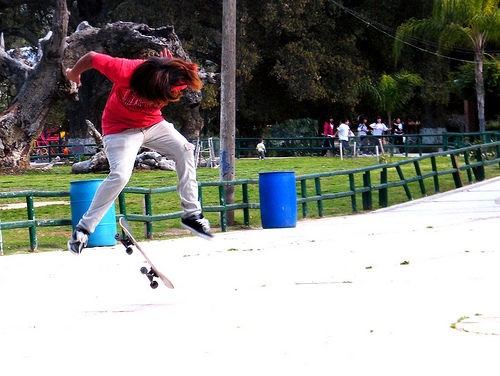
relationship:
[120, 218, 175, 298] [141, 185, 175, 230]
skateboard jumps into air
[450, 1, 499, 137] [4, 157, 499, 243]
tree behind fence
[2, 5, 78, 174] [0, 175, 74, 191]
tree standing above grass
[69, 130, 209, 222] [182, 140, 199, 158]
pants has torn out knee patch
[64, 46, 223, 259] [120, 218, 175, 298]
skateboarder jumps up with skateboard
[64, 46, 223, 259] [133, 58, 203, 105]
skateboarder has flying hair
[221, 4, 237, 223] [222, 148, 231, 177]
utility pole has a paint spot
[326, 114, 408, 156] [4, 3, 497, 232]
people garing in park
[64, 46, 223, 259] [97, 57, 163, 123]
skateboarder wearing t-shirt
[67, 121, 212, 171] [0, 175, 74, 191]
branch lies on grass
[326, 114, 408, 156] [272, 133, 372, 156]
people standing near cars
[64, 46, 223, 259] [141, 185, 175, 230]
skateboarder performing tricks in air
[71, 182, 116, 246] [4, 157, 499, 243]
garbage can in front of fence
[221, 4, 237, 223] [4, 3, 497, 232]
pole inside a park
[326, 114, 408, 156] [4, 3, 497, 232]
people are walking inside a park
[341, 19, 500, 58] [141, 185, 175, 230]
telephone wires hang in air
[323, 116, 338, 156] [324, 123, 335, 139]
woman wearing shirt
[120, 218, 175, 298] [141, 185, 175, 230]
skateboard flying in air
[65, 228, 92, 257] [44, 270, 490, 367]
feet above ground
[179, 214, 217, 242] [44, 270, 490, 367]
feet above ground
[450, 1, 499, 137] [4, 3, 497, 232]
lush tree inside a park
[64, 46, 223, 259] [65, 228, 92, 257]
boy wears shoes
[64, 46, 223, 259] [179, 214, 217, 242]
boy wears shoes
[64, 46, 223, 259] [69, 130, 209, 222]
man wears pants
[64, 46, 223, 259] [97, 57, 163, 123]
boy has on a t-shirt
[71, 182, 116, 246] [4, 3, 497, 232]
trash can inside park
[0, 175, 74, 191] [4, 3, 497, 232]
grass covers park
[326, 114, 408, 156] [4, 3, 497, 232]
people walking inside park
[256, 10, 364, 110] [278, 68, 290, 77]
tree have leaves